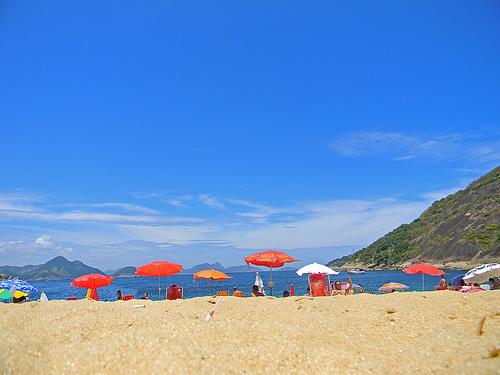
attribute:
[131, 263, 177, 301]
umbrella — red, open, orange, white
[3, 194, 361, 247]
clouds — white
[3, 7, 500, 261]
sky — blue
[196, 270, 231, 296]
umbrella — orange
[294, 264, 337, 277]
umbrella — white, open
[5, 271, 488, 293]
ocean — blue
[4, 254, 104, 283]
mountain — large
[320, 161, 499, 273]
mountain — green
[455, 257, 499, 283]
umbrella — blue, white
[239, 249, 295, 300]
umbrella — open